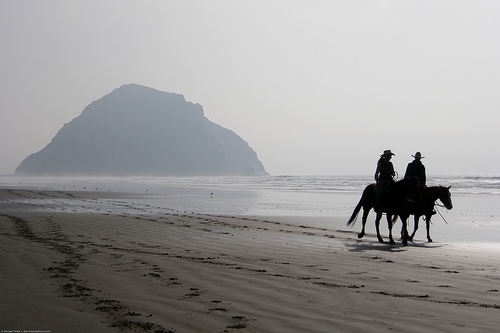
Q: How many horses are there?
A: 2.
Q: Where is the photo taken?
A: Beach.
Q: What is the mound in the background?
A: A hill.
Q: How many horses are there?
A: 2.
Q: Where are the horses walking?
A: Beach.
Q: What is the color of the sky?
A: Gray.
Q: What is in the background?
A: Small island.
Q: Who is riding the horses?
A: A couple.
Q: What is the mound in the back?
A: A mountain.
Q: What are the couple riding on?
A: Horses.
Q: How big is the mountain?
A: Tall.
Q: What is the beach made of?
A: Sand.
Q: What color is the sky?
A: Gray.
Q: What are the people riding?
A: Horses.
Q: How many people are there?
A: Two.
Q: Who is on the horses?
A: Two people.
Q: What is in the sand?
A: Footprints.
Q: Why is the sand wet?
A: There is water lapping.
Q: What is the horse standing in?
A: Sand.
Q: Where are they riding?
A: At the beach.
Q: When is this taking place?
A: During the day.